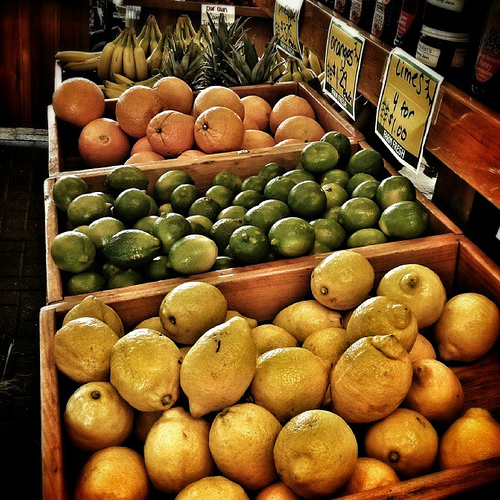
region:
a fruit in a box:
[76, 447, 142, 497]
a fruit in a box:
[148, 402, 210, 484]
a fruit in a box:
[270, 399, 361, 492]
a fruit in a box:
[211, 404, 281, 490]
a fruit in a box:
[183, 314, 256, 416]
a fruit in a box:
[105, 327, 179, 406]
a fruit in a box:
[57, 375, 132, 449]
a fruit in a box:
[432, 288, 497, 373]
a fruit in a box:
[309, 249, 372, 310]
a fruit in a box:
[156, 275, 226, 337]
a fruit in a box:
[170, 233, 215, 273]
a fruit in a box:
[269, 203, 317, 253]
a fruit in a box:
[377, 200, 420, 230]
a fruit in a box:
[53, 230, 94, 266]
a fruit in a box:
[88, 216, 119, 243]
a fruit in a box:
[115, 187, 147, 214]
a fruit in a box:
[68, 191, 105, 216]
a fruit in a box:
[56, 172, 86, 200]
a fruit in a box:
[166, 175, 196, 205]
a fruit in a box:
[233, 183, 260, 204]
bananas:
[53, 25, 214, 89]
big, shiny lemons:
[31, 292, 498, 494]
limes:
[37, 170, 442, 251]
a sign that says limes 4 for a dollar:
[363, 50, 448, 167]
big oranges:
[45, 92, 329, 157]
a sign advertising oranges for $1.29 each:
[324, 20, 354, 117]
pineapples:
[157, 12, 305, 94]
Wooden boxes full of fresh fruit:
[38, 96, 496, 491]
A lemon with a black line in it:
[185, 307, 253, 412]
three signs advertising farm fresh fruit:
[274, 10, 427, 202]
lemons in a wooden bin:
[47, 307, 499, 477]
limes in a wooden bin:
[41, 132, 434, 286]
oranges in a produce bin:
[36, 77, 401, 169]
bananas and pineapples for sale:
[51, 10, 316, 87]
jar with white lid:
[411, 20, 468, 76]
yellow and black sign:
[370, 45, 451, 179]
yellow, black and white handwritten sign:
[316, 17, 366, 126]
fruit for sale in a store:
[41, 38, 464, 276]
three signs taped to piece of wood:
[268, 1, 445, 174]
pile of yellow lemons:
[40, 300, 475, 495]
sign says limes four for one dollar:
[368, 40, 456, 199]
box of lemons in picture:
[39, 302, 477, 498]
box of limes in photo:
[45, 162, 442, 251]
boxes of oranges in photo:
[47, 83, 358, 168]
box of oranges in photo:
[71, 19, 313, 87]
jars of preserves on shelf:
[343, 0, 498, 110]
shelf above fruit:
[280, 0, 498, 155]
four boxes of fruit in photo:
[39, 37, 421, 491]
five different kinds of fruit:
[62, 31, 455, 497]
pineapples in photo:
[146, 39, 323, 94]